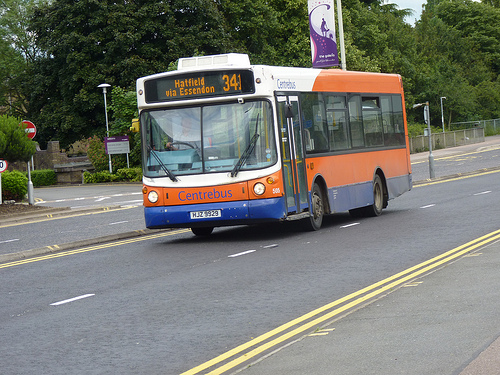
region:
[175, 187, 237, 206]
Centrebus on front of bus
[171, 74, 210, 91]
Sign says Hatfield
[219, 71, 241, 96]
Bus number is 34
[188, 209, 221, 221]
License plate on bus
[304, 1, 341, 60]
Purple and white banner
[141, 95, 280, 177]
Window on front of bus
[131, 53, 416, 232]
Bus driving down the street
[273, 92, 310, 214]
Door on bus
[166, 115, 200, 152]
Driver of bus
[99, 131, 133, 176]
Sign on the street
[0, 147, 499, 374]
a large asphalt road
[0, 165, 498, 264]
a curb dividing the road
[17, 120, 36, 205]
a sign in a driveway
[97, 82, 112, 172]
a metal light pole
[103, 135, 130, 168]
a sign in a driveway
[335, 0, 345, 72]
a tall metal post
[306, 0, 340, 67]
a banner on the post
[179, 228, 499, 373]
a pair of yellow lines on the road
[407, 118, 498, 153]
a chain link fence in the background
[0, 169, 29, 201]
a bush in a driveway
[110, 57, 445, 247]
The train is on the street.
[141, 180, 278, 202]
The lights are on.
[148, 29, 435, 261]
The bus is orange.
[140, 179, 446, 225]
The bottom of the bus is blue.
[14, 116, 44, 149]
The sign is behind the tree.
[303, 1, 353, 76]
The flag is white and purple.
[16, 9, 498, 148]
The trees are green.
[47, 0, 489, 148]
The trees are leafy.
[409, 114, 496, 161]
The fence is silver.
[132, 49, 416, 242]
a bus is on a freeway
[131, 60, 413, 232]
the bus is blue, orange, and white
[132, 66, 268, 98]
the marquee displays the destination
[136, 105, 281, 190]
the front windows of the bus are large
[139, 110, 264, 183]
the windows have windshield wipers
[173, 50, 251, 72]
an air conditioner unit is on the bus roof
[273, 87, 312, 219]
the doors of the bus are on the side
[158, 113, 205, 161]
the bus driver has a hand on the steering wheel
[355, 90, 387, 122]
a window is open on the bus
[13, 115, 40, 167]
a do not enter sign is by the road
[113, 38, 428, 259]
bus on the road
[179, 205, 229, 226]
license plate of a bus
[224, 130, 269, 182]
windshield wiper on a bus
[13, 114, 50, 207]
sign on a pole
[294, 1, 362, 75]
banner on a pole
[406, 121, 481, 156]
fence by a sidewalk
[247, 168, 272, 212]
headlight on a bus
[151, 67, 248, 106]
route of a bus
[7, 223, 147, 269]
median in the road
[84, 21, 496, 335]
bus on the road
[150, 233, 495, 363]
yellow lines on the ground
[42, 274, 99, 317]
a white line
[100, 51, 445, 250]
bus on the road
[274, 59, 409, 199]
orange side of bus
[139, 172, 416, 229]
blue trim on bus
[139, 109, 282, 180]
front windows on bus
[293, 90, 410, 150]
a row of windows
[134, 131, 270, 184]
a pair of windshield wipers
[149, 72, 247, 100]
digital sign on the bus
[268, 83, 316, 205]
doors on the bus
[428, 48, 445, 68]
green leaves on the tree